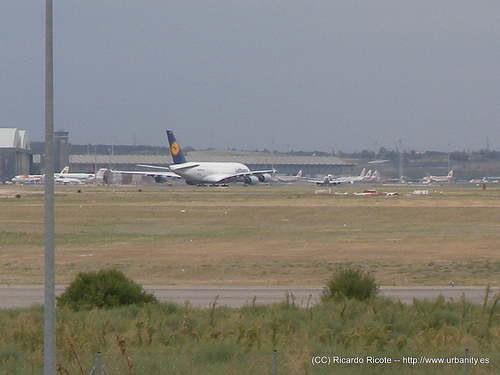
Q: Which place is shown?
A: It is an airport.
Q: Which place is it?
A: It is an airport.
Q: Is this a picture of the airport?
A: Yes, it is showing the airport.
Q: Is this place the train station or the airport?
A: It is the airport.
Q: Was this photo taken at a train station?
A: No, the picture was taken in an airport.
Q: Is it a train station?
A: No, it is an airport.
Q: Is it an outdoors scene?
A: Yes, it is outdoors.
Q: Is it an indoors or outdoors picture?
A: It is outdoors.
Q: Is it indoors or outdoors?
A: It is outdoors.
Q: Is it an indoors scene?
A: No, it is outdoors.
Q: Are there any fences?
A: No, there are no fences.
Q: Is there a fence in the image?
A: No, there are no fences.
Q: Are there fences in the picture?
A: No, there are no fences.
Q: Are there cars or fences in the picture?
A: No, there are no fences or cars.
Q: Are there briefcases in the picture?
A: No, there are no briefcases.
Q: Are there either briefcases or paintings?
A: No, there are no briefcases or paintings.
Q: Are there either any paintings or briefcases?
A: No, there are no briefcases or paintings.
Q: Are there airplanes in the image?
A: Yes, there is an airplane.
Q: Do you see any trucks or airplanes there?
A: Yes, there is an airplane.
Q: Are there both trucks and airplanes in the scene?
A: No, there is an airplane but no trucks.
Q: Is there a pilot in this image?
A: No, there are no pilots.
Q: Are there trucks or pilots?
A: No, there are no pilots or trucks.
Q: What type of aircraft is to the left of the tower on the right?
A: The aircraft is an airplane.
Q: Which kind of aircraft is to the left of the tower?
A: The aircraft is an airplane.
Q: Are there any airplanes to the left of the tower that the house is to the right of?
A: Yes, there is an airplane to the left of the tower.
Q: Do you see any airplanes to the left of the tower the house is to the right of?
A: Yes, there is an airplane to the left of the tower.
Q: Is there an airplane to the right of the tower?
A: No, the airplane is to the left of the tower.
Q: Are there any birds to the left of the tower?
A: No, there is an airplane to the left of the tower.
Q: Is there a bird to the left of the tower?
A: No, there is an airplane to the left of the tower.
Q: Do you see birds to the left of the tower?
A: No, there is an airplane to the left of the tower.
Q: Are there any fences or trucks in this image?
A: No, there are no fences or trucks.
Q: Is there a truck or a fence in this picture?
A: No, there are no fences or trucks.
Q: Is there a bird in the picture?
A: No, there are no birds.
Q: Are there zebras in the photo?
A: No, there are no zebras.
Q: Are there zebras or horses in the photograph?
A: No, there are no zebras or horses.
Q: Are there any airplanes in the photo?
A: Yes, there is an airplane.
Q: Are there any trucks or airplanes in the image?
A: Yes, there is an airplane.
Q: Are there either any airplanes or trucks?
A: Yes, there is an airplane.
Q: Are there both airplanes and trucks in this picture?
A: No, there is an airplane but no trucks.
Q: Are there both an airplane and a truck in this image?
A: No, there is an airplane but no trucks.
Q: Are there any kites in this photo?
A: No, there are no kites.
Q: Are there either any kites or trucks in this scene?
A: No, there are no kites or trucks.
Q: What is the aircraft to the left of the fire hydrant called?
A: The aircraft is an airplane.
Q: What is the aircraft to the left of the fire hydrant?
A: The aircraft is an airplane.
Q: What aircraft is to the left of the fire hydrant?
A: The aircraft is an airplane.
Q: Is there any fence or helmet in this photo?
A: No, there are no fences or helmets.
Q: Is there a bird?
A: No, there are no birds.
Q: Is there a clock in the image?
A: No, there are no clocks.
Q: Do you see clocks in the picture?
A: No, there are no clocks.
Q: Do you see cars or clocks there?
A: No, there are no clocks or cars.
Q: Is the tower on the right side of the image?
A: Yes, the tower is on the right of the image.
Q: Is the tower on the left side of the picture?
A: No, the tower is on the right of the image.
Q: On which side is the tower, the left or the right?
A: The tower is on the right of the image.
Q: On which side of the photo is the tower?
A: The tower is on the right of the image.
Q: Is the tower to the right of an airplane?
A: Yes, the tower is to the right of an airplane.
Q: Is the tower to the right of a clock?
A: No, the tower is to the right of an airplane.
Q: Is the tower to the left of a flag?
A: No, the tower is to the left of a house.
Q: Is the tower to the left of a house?
A: Yes, the tower is to the left of a house.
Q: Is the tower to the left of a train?
A: No, the tower is to the left of a house.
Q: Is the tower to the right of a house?
A: No, the tower is to the left of a house.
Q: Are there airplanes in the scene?
A: Yes, there are airplanes.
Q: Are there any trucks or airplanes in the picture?
A: Yes, there are airplanes.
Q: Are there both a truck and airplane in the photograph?
A: No, there are airplanes but no trucks.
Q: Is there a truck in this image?
A: No, there are no trucks.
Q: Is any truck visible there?
A: No, there are no trucks.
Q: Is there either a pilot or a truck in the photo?
A: No, there are no trucks or pilots.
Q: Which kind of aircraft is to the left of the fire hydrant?
A: The aircraft is airplanes.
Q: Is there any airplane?
A: Yes, there is an airplane.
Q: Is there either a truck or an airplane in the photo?
A: Yes, there is an airplane.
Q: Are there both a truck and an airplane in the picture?
A: No, there is an airplane but no trucks.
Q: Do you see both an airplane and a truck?
A: No, there is an airplane but no trucks.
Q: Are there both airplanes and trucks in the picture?
A: No, there is an airplane but no trucks.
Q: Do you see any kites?
A: No, there are no kites.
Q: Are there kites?
A: No, there are no kites.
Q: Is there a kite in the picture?
A: No, there are no kites.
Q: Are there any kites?
A: No, there are no kites.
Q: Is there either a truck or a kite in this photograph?
A: No, there are no kites or trucks.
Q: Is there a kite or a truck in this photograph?
A: No, there are no kites or trucks.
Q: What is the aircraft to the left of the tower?
A: The aircraft is an airplane.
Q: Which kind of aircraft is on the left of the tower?
A: The aircraft is an airplane.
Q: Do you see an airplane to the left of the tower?
A: Yes, there is an airplane to the left of the tower.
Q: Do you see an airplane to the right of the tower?
A: No, the airplane is to the left of the tower.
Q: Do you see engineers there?
A: No, there are no engineers.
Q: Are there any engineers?
A: No, there are no engineers.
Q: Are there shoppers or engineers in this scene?
A: No, there are no engineers or shoppers.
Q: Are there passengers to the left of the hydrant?
A: Yes, there is a passenger to the left of the hydrant.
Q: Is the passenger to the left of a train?
A: No, the passenger is to the left of the hydrant.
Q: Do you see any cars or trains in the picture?
A: No, there are no cars or trains.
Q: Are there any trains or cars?
A: No, there are no cars or trains.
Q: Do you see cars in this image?
A: No, there are no cars.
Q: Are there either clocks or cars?
A: No, there are no cars or clocks.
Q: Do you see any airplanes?
A: Yes, there are airplanes.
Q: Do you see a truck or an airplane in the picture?
A: Yes, there are airplanes.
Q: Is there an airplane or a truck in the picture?
A: Yes, there are airplanes.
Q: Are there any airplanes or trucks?
A: Yes, there are airplanes.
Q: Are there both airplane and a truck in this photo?
A: No, there are airplanes but no trucks.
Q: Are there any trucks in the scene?
A: No, there are no trucks.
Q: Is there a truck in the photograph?
A: No, there are no trucks.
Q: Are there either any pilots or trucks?
A: No, there are no trucks or pilots.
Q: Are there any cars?
A: No, there are no cars.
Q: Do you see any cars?
A: No, there are no cars.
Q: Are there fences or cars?
A: No, there are no cars or fences.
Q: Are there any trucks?
A: No, there are no trucks.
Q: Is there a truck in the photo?
A: No, there are no trucks.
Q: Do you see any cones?
A: No, there are no cones.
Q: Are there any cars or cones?
A: No, there are no cones or cars.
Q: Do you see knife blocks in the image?
A: No, there are no knife blocks.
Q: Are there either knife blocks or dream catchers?
A: No, there are no knife blocks or dream catchers.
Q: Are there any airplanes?
A: Yes, there are airplanes.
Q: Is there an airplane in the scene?
A: Yes, there are airplanes.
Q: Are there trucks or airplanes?
A: Yes, there are airplanes.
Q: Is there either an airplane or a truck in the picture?
A: Yes, there are airplanes.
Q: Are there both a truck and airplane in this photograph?
A: No, there are airplanes but no trucks.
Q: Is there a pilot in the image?
A: No, there are no pilots.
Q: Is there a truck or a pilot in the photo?
A: No, there are no pilots or trucks.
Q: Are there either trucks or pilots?
A: No, there are no pilots or trucks.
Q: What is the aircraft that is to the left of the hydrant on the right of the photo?
A: The aircraft is airplanes.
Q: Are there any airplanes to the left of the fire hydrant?
A: Yes, there are airplanes to the left of the fire hydrant.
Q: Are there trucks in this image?
A: No, there are no trucks.